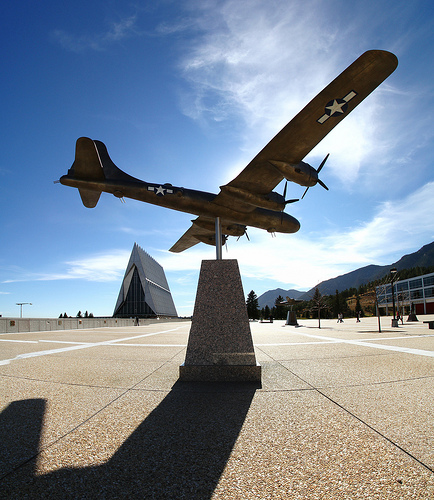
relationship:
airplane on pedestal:
[60, 46, 402, 256] [175, 259, 263, 385]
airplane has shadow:
[60, 46, 402, 256] [3, 379, 265, 499]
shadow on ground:
[3, 379, 265, 499] [3, 320, 433, 498]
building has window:
[375, 272, 433, 322] [373, 283, 387, 295]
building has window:
[375, 272, 433, 322] [394, 281, 410, 293]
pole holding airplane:
[210, 215, 226, 260] [60, 46, 402, 256]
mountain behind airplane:
[252, 285, 307, 312] [60, 46, 402, 256]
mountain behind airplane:
[301, 263, 382, 297] [60, 46, 402, 256]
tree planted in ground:
[246, 291, 260, 323] [3, 320, 433, 498]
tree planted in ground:
[310, 288, 329, 329] [3, 320, 433, 498]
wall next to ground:
[3, 313, 188, 336] [3, 320, 433, 498]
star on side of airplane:
[154, 186, 167, 198] [60, 46, 402, 256]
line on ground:
[330, 334, 431, 371] [3, 320, 433, 498]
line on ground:
[5, 335, 103, 380] [3, 320, 433, 498]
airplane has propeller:
[60, 46, 402, 256] [270, 155, 332, 195]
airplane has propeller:
[60, 46, 402, 256] [233, 182, 297, 211]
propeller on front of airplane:
[220, 221, 254, 243] [60, 46, 402, 256]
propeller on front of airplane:
[197, 230, 236, 246] [60, 46, 402, 256]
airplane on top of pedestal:
[60, 46, 402, 256] [175, 259, 263, 385]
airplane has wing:
[60, 46, 402, 256] [218, 47, 402, 209]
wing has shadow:
[218, 47, 402, 209] [3, 379, 265, 499]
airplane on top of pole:
[60, 46, 402, 256] [210, 215, 226, 260]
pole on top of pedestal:
[210, 215, 226, 260] [175, 259, 263, 385]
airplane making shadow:
[60, 46, 402, 256] [3, 379, 265, 499]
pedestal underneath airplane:
[175, 259, 263, 385] [60, 46, 402, 256]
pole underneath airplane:
[210, 215, 226, 260] [60, 46, 402, 256]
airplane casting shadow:
[60, 46, 402, 256] [3, 379, 265, 499]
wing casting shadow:
[218, 47, 402, 209] [3, 379, 265, 499]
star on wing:
[325, 100, 346, 118] [218, 47, 402, 209]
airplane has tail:
[60, 46, 402, 256] [57, 137, 110, 210]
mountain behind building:
[301, 263, 382, 297] [375, 272, 433, 322]